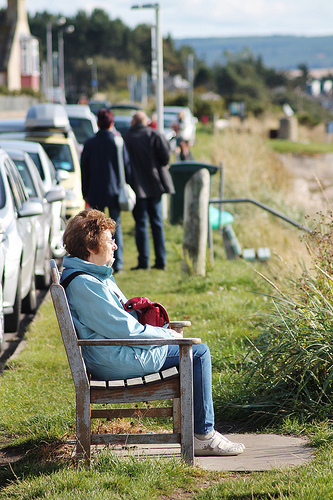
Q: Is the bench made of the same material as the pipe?
A: No, the bench is made of wood and the pipe is made of metal.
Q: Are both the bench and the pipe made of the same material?
A: No, the bench is made of wood and the pipe is made of metal.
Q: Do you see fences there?
A: No, there are no fences.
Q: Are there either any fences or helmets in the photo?
A: No, there are no fences or helmets.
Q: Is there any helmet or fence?
A: No, there are no fences or helmets.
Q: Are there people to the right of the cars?
A: Yes, there is a person to the right of the cars.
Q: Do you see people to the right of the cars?
A: Yes, there is a person to the right of the cars.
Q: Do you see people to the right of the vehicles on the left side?
A: Yes, there is a person to the right of the cars.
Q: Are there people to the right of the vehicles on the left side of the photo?
A: Yes, there is a person to the right of the cars.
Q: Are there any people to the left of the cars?
A: No, the person is to the right of the cars.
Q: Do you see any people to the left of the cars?
A: No, the person is to the right of the cars.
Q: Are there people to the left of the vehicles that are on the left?
A: No, the person is to the right of the cars.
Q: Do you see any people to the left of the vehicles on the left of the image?
A: No, the person is to the right of the cars.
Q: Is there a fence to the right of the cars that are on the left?
A: No, there is a person to the right of the cars.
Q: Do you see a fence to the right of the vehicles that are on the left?
A: No, there is a person to the right of the cars.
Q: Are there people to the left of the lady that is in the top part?
A: Yes, there is a person to the left of the lady.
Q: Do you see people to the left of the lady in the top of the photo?
A: Yes, there is a person to the left of the lady.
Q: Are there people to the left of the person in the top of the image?
A: Yes, there is a person to the left of the lady.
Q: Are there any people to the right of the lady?
A: No, the person is to the left of the lady.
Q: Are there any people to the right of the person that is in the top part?
A: No, the person is to the left of the lady.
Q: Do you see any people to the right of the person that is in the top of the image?
A: No, the person is to the left of the lady.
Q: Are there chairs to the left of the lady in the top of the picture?
A: No, there is a person to the left of the lady.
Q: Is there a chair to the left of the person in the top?
A: No, there is a person to the left of the lady.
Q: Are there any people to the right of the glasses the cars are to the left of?
A: Yes, there is a person to the right of the glasses.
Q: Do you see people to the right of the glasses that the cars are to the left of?
A: Yes, there is a person to the right of the glasses.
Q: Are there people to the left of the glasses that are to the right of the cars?
A: No, the person is to the right of the glasses.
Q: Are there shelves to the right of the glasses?
A: No, there is a person to the right of the glasses.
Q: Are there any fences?
A: No, there are no fences.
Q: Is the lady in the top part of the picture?
A: Yes, the lady is in the top of the image.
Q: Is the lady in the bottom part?
A: No, the lady is in the top of the image.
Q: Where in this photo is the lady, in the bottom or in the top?
A: The lady is in the top of the image.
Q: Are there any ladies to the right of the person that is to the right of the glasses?
A: Yes, there is a lady to the right of the person.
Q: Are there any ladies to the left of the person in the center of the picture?
A: No, the lady is to the right of the person.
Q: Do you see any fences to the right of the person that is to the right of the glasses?
A: No, there is a lady to the right of the person.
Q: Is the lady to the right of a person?
A: Yes, the lady is to the right of a person.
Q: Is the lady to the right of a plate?
A: No, the lady is to the right of a person.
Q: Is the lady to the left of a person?
A: No, the lady is to the right of a person.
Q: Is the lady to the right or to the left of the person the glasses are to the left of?
A: The lady is to the right of the person.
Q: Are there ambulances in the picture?
A: No, there are no ambulances.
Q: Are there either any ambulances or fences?
A: No, there are no ambulances or fences.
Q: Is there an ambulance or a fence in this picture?
A: No, there are no ambulances or fences.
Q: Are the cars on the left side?
A: Yes, the cars are on the left of the image.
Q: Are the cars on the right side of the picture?
A: No, the cars are on the left of the image.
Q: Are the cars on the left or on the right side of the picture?
A: The cars are on the left of the image.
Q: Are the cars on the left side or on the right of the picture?
A: The cars are on the left of the image.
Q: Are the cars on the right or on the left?
A: The cars are on the left of the image.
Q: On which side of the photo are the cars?
A: The cars are on the left of the image.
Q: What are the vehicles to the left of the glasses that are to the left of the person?
A: The vehicles are cars.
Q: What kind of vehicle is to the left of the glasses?
A: The vehicles are cars.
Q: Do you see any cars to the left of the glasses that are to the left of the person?
A: Yes, there are cars to the left of the glasses.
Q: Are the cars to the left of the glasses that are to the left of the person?
A: Yes, the cars are to the left of the glasses.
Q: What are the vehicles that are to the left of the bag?
A: The vehicles are cars.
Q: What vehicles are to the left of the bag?
A: The vehicles are cars.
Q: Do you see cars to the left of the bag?
A: Yes, there are cars to the left of the bag.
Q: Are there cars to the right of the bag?
A: No, the cars are to the left of the bag.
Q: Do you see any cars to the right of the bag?
A: No, the cars are to the left of the bag.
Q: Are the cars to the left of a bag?
A: Yes, the cars are to the left of a bag.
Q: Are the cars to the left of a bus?
A: No, the cars are to the left of a bag.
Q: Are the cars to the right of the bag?
A: No, the cars are to the left of the bag.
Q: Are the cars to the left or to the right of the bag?
A: The cars are to the left of the bag.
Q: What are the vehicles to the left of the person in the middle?
A: The vehicles are cars.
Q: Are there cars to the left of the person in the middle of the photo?
A: Yes, there are cars to the left of the person.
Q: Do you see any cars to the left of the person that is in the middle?
A: Yes, there are cars to the left of the person.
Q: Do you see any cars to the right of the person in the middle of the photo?
A: No, the cars are to the left of the person.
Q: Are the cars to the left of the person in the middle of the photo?
A: Yes, the cars are to the left of the person.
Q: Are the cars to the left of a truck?
A: No, the cars are to the left of the person.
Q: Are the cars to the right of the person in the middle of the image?
A: No, the cars are to the left of the person.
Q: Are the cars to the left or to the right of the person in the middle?
A: The cars are to the left of the person.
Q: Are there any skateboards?
A: No, there are no skateboards.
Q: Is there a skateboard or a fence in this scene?
A: No, there are no skateboards or fences.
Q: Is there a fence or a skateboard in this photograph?
A: No, there are no skateboards or fences.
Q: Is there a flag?
A: No, there are no flags.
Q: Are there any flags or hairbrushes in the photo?
A: No, there are no flags or hairbrushes.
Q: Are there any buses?
A: No, there are no buses.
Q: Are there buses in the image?
A: No, there are no buses.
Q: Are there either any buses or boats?
A: No, there are no buses or boats.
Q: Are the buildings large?
A: Yes, the buildings are large.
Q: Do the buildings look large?
A: Yes, the buildings are large.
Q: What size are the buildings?
A: The buildings are large.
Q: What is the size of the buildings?
A: The buildings are large.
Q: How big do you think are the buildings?
A: The buildings are large.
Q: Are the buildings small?
A: No, the buildings are large.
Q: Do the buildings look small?
A: No, the buildings are large.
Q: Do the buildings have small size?
A: No, the buildings are large.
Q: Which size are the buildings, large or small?
A: The buildings are large.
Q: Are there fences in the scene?
A: No, there are no fences.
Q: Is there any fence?
A: No, there are no fences.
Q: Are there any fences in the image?
A: No, there are no fences.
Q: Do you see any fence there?
A: No, there are no fences.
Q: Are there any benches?
A: Yes, there is a bench.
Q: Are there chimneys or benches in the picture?
A: Yes, there is a bench.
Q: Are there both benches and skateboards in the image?
A: No, there is a bench but no skateboards.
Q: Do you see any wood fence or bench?
A: Yes, there is a wood bench.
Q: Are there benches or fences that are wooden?
A: Yes, the bench is wooden.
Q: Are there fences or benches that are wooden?
A: Yes, the bench is wooden.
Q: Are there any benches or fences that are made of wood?
A: Yes, the bench is made of wood.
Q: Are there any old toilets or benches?
A: Yes, there is an old bench.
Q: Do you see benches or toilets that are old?
A: Yes, the bench is old.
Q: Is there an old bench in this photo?
A: Yes, there is an old bench.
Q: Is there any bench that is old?
A: Yes, there is a bench that is old.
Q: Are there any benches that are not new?
A: Yes, there is a old bench.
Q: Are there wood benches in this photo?
A: Yes, there is a wood bench.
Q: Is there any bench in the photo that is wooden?
A: Yes, there is a bench that is wooden.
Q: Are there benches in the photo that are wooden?
A: Yes, there is a bench that is wooden.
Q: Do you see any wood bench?
A: Yes, there is a bench that is made of wood.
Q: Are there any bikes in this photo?
A: No, there are no bikes.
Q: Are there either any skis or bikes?
A: No, there are no bikes or skis.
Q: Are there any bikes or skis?
A: No, there are no bikes or skis.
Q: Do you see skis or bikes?
A: No, there are no bikes or skis.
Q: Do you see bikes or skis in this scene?
A: No, there are no bikes or skis.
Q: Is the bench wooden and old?
A: Yes, the bench is wooden and old.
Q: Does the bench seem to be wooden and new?
A: No, the bench is wooden but old.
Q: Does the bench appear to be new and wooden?
A: No, the bench is wooden but old.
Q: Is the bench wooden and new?
A: No, the bench is wooden but old.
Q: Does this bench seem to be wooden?
A: Yes, the bench is wooden.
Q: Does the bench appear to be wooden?
A: Yes, the bench is wooden.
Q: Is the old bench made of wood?
A: Yes, the bench is made of wood.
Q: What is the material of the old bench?
A: The bench is made of wood.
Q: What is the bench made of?
A: The bench is made of wood.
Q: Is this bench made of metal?
A: No, the bench is made of wood.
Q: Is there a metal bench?
A: No, there is a bench but it is made of wood.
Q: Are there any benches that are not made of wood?
A: No, there is a bench but it is made of wood.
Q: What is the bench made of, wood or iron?
A: The bench is made of wood.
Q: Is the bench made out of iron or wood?
A: The bench is made of wood.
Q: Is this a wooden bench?
A: Yes, this is a wooden bench.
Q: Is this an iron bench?
A: No, this is a wooden bench.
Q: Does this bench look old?
A: Yes, the bench is old.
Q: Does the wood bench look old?
A: Yes, the bench is old.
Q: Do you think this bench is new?
A: No, the bench is old.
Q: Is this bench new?
A: No, the bench is old.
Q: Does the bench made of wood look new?
A: No, the bench is old.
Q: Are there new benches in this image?
A: No, there is a bench but it is old.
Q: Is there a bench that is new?
A: No, there is a bench but it is old.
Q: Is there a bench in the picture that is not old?
A: No, there is a bench but it is old.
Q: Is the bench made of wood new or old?
A: The bench is old.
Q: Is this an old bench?
A: Yes, this is an old bench.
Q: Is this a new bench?
A: No, this is an old bench.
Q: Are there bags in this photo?
A: Yes, there is a bag.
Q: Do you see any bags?
A: Yes, there is a bag.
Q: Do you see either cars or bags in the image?
A: Yes, there is a bag.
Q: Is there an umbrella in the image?
A: No, there are no umbrellas.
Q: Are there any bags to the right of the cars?
A: Yes, there is a bag to the right of the cars.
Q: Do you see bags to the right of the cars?
A: Yes, there is a bag to the right of the cars.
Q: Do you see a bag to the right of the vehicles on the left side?
A: Yes, there is a bag to the right of the cars.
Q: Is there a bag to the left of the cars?
A: No, the bag is to the right of the cars.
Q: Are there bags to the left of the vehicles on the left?
A: No, the bag is to the right of the cars.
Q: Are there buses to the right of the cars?
A: No, there is a bag to the right of the cars.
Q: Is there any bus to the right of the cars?
A: No, there is a bag to the right of the cars.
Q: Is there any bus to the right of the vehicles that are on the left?
A: No, there is a bag to the right of the cars.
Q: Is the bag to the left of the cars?
A: No, the bag is to the right of the cars.